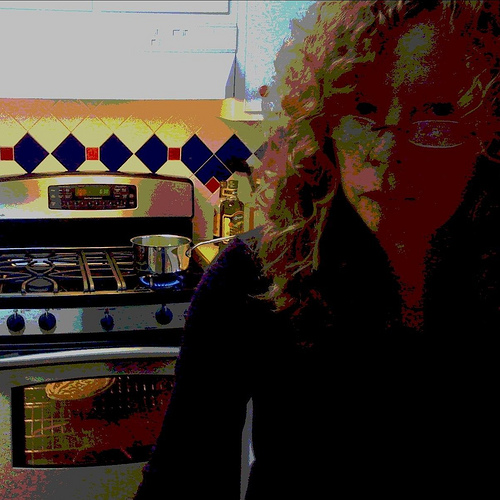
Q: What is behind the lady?
A: A stove.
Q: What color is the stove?
A: Silver.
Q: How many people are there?
A: One.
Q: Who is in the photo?
A: A lady.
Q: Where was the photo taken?
A: Kitchen.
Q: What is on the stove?
A: Pot.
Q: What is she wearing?
A: Clothes.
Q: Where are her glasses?
A: On her face.